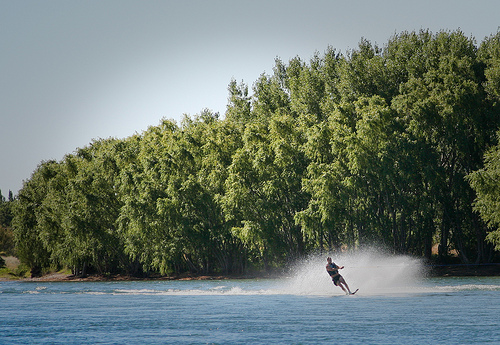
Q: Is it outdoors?
A: Yes, it is outdoors.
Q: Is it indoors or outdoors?
A: It is outdoors.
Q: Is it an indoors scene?
A: No, it is outdoors.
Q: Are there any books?
A: No, there are no books.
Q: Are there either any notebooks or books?
A: No, there are no books or notebooks.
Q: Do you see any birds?
A: No, there are no birds.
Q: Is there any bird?
A: No, there are no birds.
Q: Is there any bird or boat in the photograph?
A: No, there are no birds or boats.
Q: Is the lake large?
A: Yes, the lake is large.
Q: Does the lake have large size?
A: Yes, the lake is large.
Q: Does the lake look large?
A: Yes, the lake is large.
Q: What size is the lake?
A: The lake is large.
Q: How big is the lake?
A: The lake is large.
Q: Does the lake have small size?
A: No, the lake is large.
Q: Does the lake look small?
A: No, the lake is large.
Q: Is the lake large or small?
A: The lake is large.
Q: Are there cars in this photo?
A: No, there are no cars.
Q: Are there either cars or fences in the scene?
A: No, there are no cars or fences.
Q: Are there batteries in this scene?
A: No, there are no batteries.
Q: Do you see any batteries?
A: No, there are no batteries.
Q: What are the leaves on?
A: The leaves are on the trees.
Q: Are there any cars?
A: No, there are no cars.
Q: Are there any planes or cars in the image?
A: No, there are no cars or planes.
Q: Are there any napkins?
A: No, there are no napkins.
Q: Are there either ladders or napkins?
A: No, there are no napkins or ladders.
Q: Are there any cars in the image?
A: No, there are no cars.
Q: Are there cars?
A: No, there are no cars.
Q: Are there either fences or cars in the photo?
A: No, there are no cars or fences.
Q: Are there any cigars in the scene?
A: No, there are no cigars.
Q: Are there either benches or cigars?
A: No, there are no cigars or benches.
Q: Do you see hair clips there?
A: No, there are no hair clips.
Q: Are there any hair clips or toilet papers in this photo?
A: No, there are no hair clips or toilet papers.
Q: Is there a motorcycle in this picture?
A: No, there are no motorcycles.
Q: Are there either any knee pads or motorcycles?
A: No, there are no motorcycles or knee pads.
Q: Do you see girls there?
A: No, there are no girls.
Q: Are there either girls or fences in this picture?
A: No, there are no girls or fences.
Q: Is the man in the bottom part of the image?
A: Yes, the man is in the bottom of the image.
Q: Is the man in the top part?
A: No, the man is in the bottom of the image.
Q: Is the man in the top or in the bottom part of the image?
A: The man is in the bottom of the image.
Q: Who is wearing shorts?
A: The man is wearing shorts.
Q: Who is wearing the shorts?
A: The man is wearing shorts.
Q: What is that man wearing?
A: The man is wearing shorts.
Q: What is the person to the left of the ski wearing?
A: The man is wearing shorts.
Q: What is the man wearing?
A: The man is wearing shorts.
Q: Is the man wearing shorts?
A: Yes, the man is wearing shorts.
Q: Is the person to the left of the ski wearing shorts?
A: Yes, the man is wearing shorts.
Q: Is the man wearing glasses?
A: No, the man is wearing shorts.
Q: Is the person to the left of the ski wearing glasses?
A: No, the man is wearing shorts.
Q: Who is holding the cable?
A: The man is holding the cable.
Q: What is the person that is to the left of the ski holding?
A: The man is holding the cable.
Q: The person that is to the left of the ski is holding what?
A: The man is holding the cable.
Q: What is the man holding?
A: The man is holding the cable.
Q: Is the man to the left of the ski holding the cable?
A: Yes, the man is holding the cable.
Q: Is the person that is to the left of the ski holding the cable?
A: Yes, the man is holding the cable.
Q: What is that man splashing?
A: The man is splashing the water.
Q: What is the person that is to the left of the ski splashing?
A: The man is splashing the water.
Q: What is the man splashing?
A: The man is splashing the water.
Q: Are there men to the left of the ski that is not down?
A: Yes, there is a man to the left of the ski.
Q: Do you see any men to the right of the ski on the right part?
A: No, the man is to the left of the ski.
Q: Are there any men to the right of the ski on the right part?
A: No, the man is to the left of the ski.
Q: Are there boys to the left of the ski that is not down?
A: No, there is a man to the left of the ski.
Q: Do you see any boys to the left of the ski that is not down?
A: No, there is a man to the left of the ski.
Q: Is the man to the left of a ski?
A: Yes, the man is to the left of a ski.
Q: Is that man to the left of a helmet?
A: No, the man is to the left of a ski.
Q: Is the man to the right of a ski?
A: No, the man is to the left of a ski.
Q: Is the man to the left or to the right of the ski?
A: The man is to the left of the ski.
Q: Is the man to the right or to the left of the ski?
A: The man is to the left of the ski.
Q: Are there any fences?
A: No, there are no fences.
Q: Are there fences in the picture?
A: No, there are no fences.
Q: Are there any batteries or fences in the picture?
A: No, there are no fences or batteries.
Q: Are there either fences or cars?
A: No, there are no fences or cars.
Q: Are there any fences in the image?
A: No, there are no fences.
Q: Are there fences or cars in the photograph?
A: No, there are no fences or cars.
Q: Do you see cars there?
A: No, there are no cars.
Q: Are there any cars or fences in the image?
A: No, there are no cars or fences.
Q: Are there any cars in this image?
A: No, there are no cars.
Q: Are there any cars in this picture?
A: No, there are no cars.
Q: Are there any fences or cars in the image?
A: No, there are no cars or fences.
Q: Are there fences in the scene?
A: No, there are no fences.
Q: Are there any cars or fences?
A: No, there are no fences or cars.